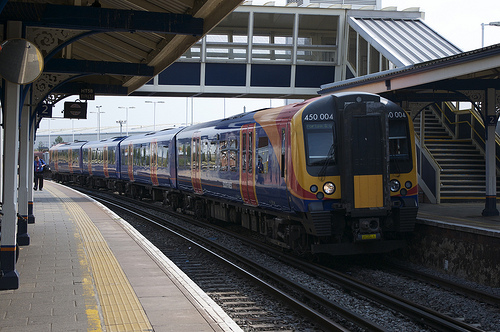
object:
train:
[49, 87, 421, 268]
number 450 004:
[300, 112, 335, 123]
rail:
[230, 254, 500, 307]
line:
[421, 208, 500, 232]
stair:
[419, 138, 486, 164]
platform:
[412, 196, 499, 235]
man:
[32, 153, 48, 191]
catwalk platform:
[134, 3, 344, 96]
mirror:
[2, 35, 46, 85]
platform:
[0, 154, 244, 332]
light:
[320, 182, 336, 196]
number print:
[385, 110, 409, 120]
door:
[238, 121, 263, 210]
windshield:
[303, 120, 339, 175]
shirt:
[34, 155, 50, 174]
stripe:
[70, 178, 135, 328]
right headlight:
[309, 183, 319, 194]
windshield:
[385, 117, 411, 168]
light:
[479, 15, 499, 50]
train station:
[1, 0, 500, 331]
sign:
[62, 100, 89, 121]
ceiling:
[0, 0, 245, 97]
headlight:
[390, 180, 403, 194]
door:
[187, 128, 207, 197]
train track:
[84, 165, 431, 331]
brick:
[29, 314, 82, 324]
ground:
[0, 175, 244, 331]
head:
[33, 150, 41, 161]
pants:
[34, 168, 45, 194]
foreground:
[0, 91, 499, 331]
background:
[2, 0, 499, 193]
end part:
[287, 90, 425, 261]